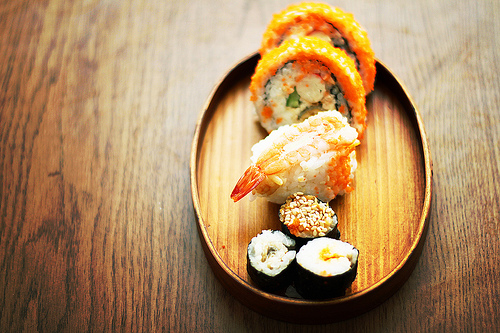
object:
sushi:
[245, 229, 296, 292]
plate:
[186, 50, 434, 326]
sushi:
[291, 235, 360, 300]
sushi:
[276, 192, 340, 243]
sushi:
[230, 110, 360, 207]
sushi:
[248, 36, 367, 145]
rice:
[249, 111, 357, 208]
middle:
[225, 110, 364, 205]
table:
[0, 0, 499, 332]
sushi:
[258, 3, 377, 96]